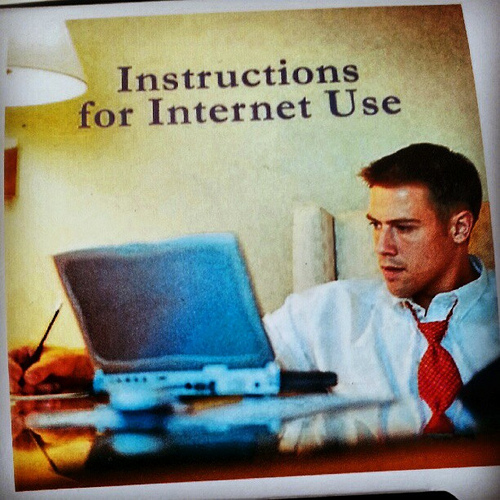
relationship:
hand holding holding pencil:
[10, 349, 70, 392] [15, 301, 66, 381]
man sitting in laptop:
[257, 139, 500, 459] [50, 233, 341, 396]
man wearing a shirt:
[257, 139, 500, 459] [248, 228, 486, 400]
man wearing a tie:
[257, 139, 500, 459] [418, 272, 488, 426]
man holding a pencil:
[241, 131, 498, 389] [21, 296, 67, 355]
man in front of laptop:
[257, 139, 500, 459] [50, 233, 341, 396]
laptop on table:
[49, 224, 344, 408] [11, 377, 498, 497]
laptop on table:
[49, 249, 312, 408] [13, 376, 425, 498]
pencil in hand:
[15, 305, 70, 367] [6, 323, 97, 406]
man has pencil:
[257, 139, 500, 459] [15, 305, 70, 367]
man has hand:
[257, 139, 500, 459] [6, 323, 97, 406]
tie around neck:
[407, 301, 464, 436] [429, 262, 475, 304]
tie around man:
[407, 301, 464, 436] [267, 142, 498, 458]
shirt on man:
[258, 251, 498, 412] [250, 133, 495, 456]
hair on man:
[364, 139, 483, 211] [19, 144, 489, 404]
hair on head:
[364, 139, 483, 211] [361, 140, 482, 295]